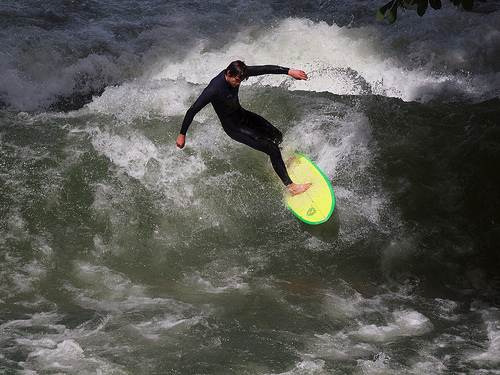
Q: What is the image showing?
A: It is showing an ocean.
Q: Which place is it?
A: It is an ocean.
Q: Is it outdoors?
A: Yes, it is outdoors.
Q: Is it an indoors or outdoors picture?
A: It is outdoors.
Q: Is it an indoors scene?
A: No, it is outdoors.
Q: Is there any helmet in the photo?
A: No, there are no helmets.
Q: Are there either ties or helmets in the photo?
A: No, there are no helmets or ties.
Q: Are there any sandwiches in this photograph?
A: Yes, there is a sandwich.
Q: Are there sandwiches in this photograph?
A: Yes, there is a sandwich.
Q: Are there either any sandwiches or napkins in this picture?
A: Yes, there is a sandwich.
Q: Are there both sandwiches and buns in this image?
A: No, there is a sandwich but no buns.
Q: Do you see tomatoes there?
A: No, there are no tomatoes.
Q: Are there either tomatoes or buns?
A: No, there are no tomatoes or buns.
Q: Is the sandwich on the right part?
A: Yes, the sandwich is on the right of the image.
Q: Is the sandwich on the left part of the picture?
A: No, the sandwich is on the right of the image.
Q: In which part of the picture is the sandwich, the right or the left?
A: The sandwich is on the right of the image.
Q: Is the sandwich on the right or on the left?
A: The sandwich is on the right of the image.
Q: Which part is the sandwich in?
A: The sandwich is on the right of the image.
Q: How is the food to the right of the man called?
A: The food is a sandwich.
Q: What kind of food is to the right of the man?
A: The food is a sandwich.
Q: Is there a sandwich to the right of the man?
A: Yes, there is a sandwich to the right of the man.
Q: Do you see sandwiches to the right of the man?
A: Yes, there is a sandwich to the right of the man.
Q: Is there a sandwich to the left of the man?
A: No, the sandwich is to the right of the man.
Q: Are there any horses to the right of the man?
A: No, there is a sandwich to the right of the man.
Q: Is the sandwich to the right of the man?
A: Yes, the sandwich is to the right of the man.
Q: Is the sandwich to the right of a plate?
A: No, the sandwich is to the right of the man.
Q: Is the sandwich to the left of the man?
A: No, the sandwich is to the right of the man.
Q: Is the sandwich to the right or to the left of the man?
A: The sandwich is to the right of the man.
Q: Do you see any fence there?
A: No, there are no fences.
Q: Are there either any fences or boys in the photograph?
A: No, there are no fences or boys.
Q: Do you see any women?
A: No, there are no women.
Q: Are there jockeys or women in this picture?
A: No, there are no women or jockeys.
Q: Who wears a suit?
A: The man wears a suit.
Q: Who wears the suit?
A: The man wears a suit.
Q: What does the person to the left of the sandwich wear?
A: The man wears a suit.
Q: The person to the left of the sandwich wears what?
A: The man wears a suit.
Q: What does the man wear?
A: The man wears a suit.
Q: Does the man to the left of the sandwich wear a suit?
A: Yes, the man wears a suit.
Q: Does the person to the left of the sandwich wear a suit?
A: Yes, the man wears a suit.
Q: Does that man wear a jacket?
A: No, the man wears a suit.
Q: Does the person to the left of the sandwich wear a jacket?
A: No, the man wears a suit.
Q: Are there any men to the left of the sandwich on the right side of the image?
A: Yes, there is a man to the left of the sandwich.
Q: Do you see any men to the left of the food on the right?
A: Yes, there is a man to the left of the sandwich.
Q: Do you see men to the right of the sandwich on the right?
A: No, the man is to the left of the sandwich.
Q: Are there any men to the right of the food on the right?
A: No, the man is to the left of the sandwich.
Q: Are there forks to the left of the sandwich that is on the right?
A: No, there is a man to the left of the sandwich.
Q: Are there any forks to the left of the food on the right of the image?
A: No, there is a man to the left of the sandwich.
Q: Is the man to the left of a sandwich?
A: Yes, the man is to the left of a sandwich.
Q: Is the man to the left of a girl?
A: No, the man is to the left of a sandwich.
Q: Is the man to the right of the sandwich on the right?
A: No, the man is to the left of the sandwich.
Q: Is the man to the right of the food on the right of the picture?
A: No, the man is to the left of the sandwich.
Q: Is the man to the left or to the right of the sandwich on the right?
A: The man is to the left of the sandwich.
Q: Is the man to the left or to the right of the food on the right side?
A: The man is to the left of the sandwich.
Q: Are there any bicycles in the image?
A: No, there are no bicycles.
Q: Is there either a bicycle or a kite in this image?
A: No, there are no bicycles or kites.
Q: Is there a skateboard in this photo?
A: No, there are no skateboards.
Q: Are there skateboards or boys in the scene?
A: No, there are no skateboards or boys.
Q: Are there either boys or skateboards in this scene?
A: No, there are no skateboards or boys.